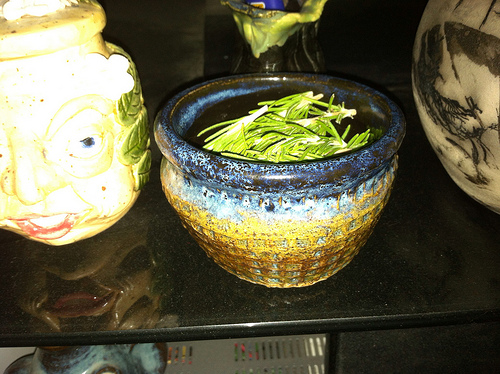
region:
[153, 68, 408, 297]
bowl full of reeds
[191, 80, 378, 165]
small pile of pine needles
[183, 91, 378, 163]
pine needles are green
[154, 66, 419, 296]
irridescent bown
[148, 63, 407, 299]
bowl is blue, yellow and brown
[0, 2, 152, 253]
vase looks like a face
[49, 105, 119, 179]
eye of face on vase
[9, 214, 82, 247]
mouth of face on vase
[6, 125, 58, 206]
nose of face on vase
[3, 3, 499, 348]
vases on a black table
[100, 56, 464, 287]
a bowl of grass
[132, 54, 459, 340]
a bowl of green grass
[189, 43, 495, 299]
a bowl on a table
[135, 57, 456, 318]
a ceramic bowl on a table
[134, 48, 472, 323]
a table with a ceramic bowl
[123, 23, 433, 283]
a bowl that is inside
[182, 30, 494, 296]
a ceramic bowl that is inside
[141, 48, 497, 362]
a bowl that is field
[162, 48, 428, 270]
a ceramic bowl that is filled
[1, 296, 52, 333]
part of Reflective black table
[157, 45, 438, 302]
Decotative vase on table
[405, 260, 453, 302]
part of Reflective black table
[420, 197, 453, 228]
part of Reflective black table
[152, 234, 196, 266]
part of Reflective black table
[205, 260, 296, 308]
part of Reflective black table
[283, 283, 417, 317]
part of Reflective black table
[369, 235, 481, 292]
part of Reflective black table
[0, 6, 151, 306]
Decorative vase on table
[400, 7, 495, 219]
Decorative vase on table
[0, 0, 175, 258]
a ceramic bowl with a face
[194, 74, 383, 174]
herbs inside a bowl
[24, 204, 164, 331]
reflections off the table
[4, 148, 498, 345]
a black marble table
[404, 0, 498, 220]
a urn designed in beige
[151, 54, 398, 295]
textures on the side of the bowl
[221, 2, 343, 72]
reflections from the table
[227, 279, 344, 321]
reflections off the table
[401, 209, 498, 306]
reflections off the marble table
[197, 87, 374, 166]
fresh rosemary in ceramic bowl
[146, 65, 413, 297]
ceramic bowl on shelf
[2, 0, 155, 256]
ceramic cookie jar with face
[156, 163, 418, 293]
gold honeycomb style portion of bowl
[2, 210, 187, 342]
reflection of cookie jar in glass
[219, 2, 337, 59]
light green ceramic leaf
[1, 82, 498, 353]
glass shelf holding ceramics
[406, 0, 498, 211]
black designs on ceramics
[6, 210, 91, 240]
red lips on ceramic face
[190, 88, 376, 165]
green sprigs of fresh rosemary